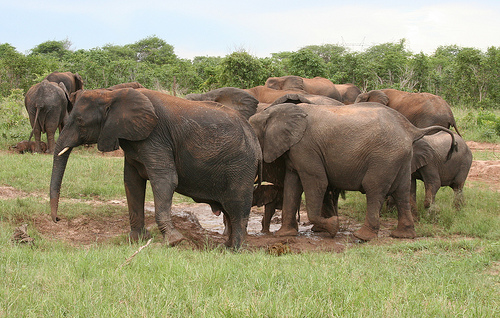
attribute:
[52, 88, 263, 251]
elephant — gray, standing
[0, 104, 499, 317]
grass — green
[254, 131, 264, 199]
tail — gray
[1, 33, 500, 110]
trees — green, leafy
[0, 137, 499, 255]
dirt — brown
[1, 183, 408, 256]
mud — brown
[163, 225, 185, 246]
foot — lifted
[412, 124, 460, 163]
tail — extended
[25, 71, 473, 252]
elephants — gray, brown, standing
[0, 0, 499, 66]
sky — bright